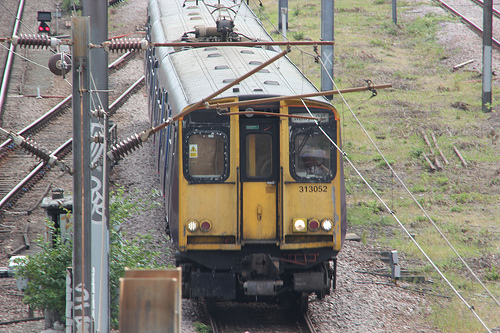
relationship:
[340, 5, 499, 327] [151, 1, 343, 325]
field near train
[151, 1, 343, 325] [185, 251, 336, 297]
train has bottom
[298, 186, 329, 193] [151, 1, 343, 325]
number on train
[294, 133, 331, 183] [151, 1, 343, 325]
window on train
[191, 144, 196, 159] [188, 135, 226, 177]
tag in window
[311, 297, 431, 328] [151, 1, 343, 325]
gravel near train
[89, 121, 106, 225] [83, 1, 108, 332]
writing on pole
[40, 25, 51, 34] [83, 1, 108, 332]
lights on pole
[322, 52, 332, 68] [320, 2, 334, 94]
x on pole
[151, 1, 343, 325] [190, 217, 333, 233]
train has lights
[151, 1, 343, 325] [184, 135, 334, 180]
train has windows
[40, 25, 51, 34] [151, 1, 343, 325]
lights on train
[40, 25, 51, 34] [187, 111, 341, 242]
lights on train rear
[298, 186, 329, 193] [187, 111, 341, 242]
number on train rear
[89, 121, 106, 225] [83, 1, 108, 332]
graffiti on pole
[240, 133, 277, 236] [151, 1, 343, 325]
door on train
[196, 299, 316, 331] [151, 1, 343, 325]
tracks for train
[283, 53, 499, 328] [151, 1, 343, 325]
lines for train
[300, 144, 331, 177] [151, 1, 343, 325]
conductor in train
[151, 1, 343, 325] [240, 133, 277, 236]
train has door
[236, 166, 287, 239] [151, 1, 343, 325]
handles on train